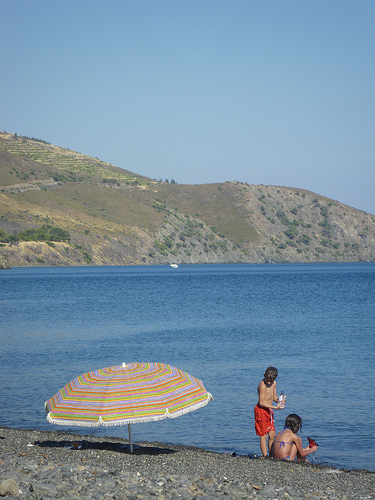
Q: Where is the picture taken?
A: The beach.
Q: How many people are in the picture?
A: Two.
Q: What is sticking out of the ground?
A: Umbrella.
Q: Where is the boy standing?
A: The water.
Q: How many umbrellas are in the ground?
A: One.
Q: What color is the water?
A: Blue.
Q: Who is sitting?
A: Girl.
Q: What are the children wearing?
A: Swimsuits.